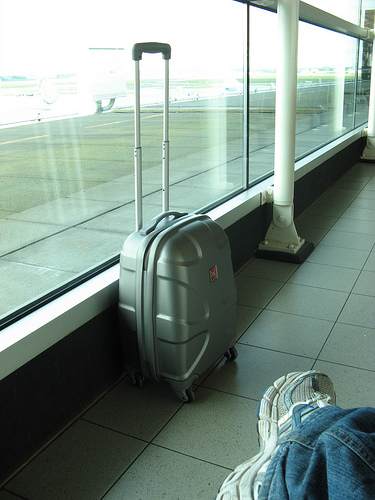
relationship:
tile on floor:
[100, 441, 234, 497] [2, 162, 373, 497]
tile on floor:
[77, 370, 200, 443] [2, 162, 373, 497]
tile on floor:
[320, 187, 366, 220] [274, 231, 357, 366]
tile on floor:
[80, 371, 187, 443] [2, 162, 373, 497]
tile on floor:
[233, 299, 346, 360] [2, 162, 373, 497]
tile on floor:
[259, 269, 359, 323] [2, 162, 373, 497]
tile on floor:
[279, 246, 369, 302] [2, 162, 373, 497]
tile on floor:
[298, 230, 373, 280] [2, 162, 373, 497]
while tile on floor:
[272, 279, 348, 326] [236, 222, 372, 364]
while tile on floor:
[329, 199, 368, 237] [236, 222, 372, 364]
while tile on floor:
[146, 403, 239, 462] [236, 222, 372, 364]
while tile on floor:
[319, 240, 365, 290] [236, 222, 372, 364]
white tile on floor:
[325, 189, 358, 232] [236, 222, 372, 364]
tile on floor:
[186, 112, 239, 183] [328, 206, 359, 290]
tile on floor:
[2, 418, 150, 497] [2, 162, 373, 497]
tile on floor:
[148, 385, 264, 470] [2, 162, 373, 497]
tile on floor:
[199, 342, 317, 400] [2, 162, 373, 497]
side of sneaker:
[155, 359, 319, 496] [204, 367, 342, 499]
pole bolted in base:
[251, 3, 313, 262] [253, 237, 314, 267]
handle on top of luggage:
[139, 209, 192, 234] [116, 211, 238, 401]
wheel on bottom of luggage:
[224, 347, 239, 360] [116, 211, 238, 401]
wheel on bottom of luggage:
[183, 389, 195, 403] [116, 211, 238, 401]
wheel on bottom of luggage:
[127, 370, 140, 386] [116, 211, 238, 401]